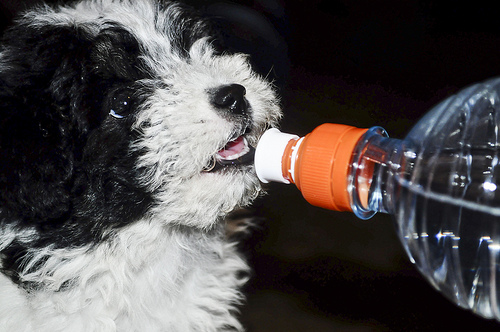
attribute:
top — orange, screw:
[251, 116, 373, 212]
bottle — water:
[249, 75, 498, 325]